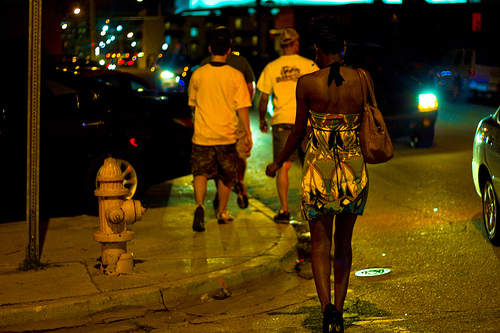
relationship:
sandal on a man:
[192, 204, 204, 231] [186, 32, 254, 233]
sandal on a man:
[215, 212, 235, 224] [186, 32, 254, 233]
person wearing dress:
[264, 36, 397, 331] [301, 106, 371, 222]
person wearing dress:
[264, 36, 397, 331] [295, 94, 377, 226]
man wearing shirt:
[186, 32, 254, 233] [185, 61, 254, 146]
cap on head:
[280, 28, 300, 45] [274, 20, 302, 59]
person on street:
[264, 36, 397, 331] [165, 155, 472, 319]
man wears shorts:
[186, 32, 254, 233] [190, 142, 247, 188]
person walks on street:
[264, 36, 397, 331] [370, 177, 469, 331]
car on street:
[472, 105, 499, 246] [248, 100, 498, 330]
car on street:
[352, 62, 437, 145] [248, 100, 498, 330]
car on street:
[149, 43, 201, 87] [248, 100, 498, 330]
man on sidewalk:
[186, 32, 254, 233] [94, 201, 284, 307]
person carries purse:
[264, 36, 397, 331] [355, 64, 396, 162]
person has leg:
[291, 36, 386, 331] [306, 209, 336, 329]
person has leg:
[264, 36, 397, 331] [191, 169, 210, 204]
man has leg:
[186, 32, 254, 233] [207, 138, 278, 237]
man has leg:
[255, 24, 325, 223] [304, 196, 338, 331]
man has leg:
[255, 24, 325, 223] [305, 210, 332, 327]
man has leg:
[255, 24, 325, 223] [332, 205, 353, 331]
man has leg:
[186, 32, 254, 233] [274, 160, 292, 223]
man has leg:
[186, 32, 254, 233] [192, 157, 207, 233]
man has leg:
[186, 32, 254, 233] [313, 220, 332, 291]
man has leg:
[255, 24, 325, 223] [335, 221, 351, 303]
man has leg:
[255, 24, 325, 223] [277, 164, 290, 205]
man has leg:
[186, 32, 254, 233] [218, 178, 235, 222]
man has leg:
[186, 32, 254, 233] [266, 156, 299, 233]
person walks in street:
[264, 36, 397, 331] [379, 177, 473, 328]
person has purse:
[264, 36, 397, 331] [363, 106, 390, 162]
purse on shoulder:
[363, 106, 390, 162] [346, 65, 377, 109]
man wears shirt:
[181, 32, 258, 222] [185, 61, 270, 155]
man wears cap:
[255, 24, 325, 223] [279, 28, 300, 46]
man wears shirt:
[186, 32, 254, 233] [183, 59, 251, 148]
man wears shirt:
[253, 24, 323, 223] [256, 52, 323, 129]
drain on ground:
[352, 264, 393, 279] [333, 241, 496, 317]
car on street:
[265, 50, 439, 149] [365, 166, 463, 330]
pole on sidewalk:
[27, 0, 46, 270] [2, 174, 307, 331]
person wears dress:
[264, 36, 397, 331] [301, 106, 371, 222]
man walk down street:
[186, 32, 254, 233] [222, 214, 310, 328]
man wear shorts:
[186, 32, 254, 233] [174, 121, 338, 174]